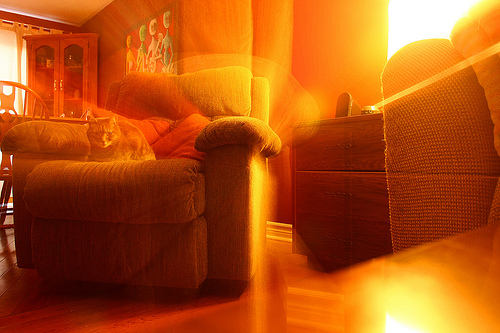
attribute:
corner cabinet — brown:
[18, 26, 103, 118]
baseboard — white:
[261, 215, 302, 246]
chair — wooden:
[2, 80, 54, 247]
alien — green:
[135, 24, 150, 71]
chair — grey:
[22, 62, 279, 310]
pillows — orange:
[0, 53, 317, 289]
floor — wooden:
[68, 282, 158, 327]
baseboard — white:
[265, 221, 292, 245]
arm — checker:
[376, 39, 498, 249]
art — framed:
[117, 16, 176, 83]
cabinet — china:
[20, 32, 103, 119]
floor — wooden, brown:
[7, 219, 498, 331]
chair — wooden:
[0, 80, 50, 237]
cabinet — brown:
[270, 116, 404, 281]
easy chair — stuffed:
[28, 92, 260, 297]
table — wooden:
[286, 107, 392, 271]